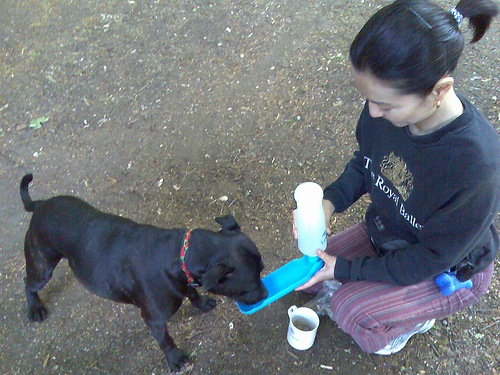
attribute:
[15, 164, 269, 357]
dog — black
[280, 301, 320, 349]
cup — white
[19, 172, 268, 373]
black dog — small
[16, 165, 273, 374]
dog — black, small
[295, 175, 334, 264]
bottle — plastic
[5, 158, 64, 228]
tail — black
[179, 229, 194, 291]
collar — red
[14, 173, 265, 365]
dog — black, short haired, small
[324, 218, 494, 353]
pants — purple, striped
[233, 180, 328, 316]
water bowl — portable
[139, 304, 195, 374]
leg — front leg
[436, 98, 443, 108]
earring — gold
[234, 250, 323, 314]
dish — blue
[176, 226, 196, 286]
collar — red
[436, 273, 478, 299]
object — plastic